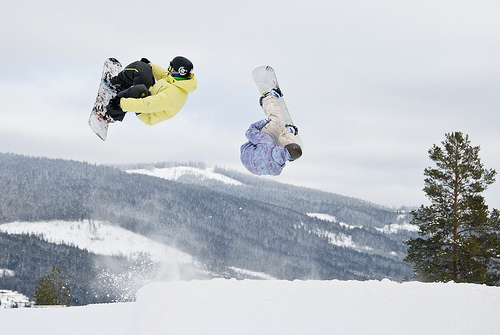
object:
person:
[239, 85, 304, 175]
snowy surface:
[93, 279, 402, 331]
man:
[239, 93, 304, 177]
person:
[102, 55, 199, 126]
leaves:
[405, 132, 497, 282]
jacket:
[119, 61, 196, 126]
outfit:
[89, 56, 198, 139]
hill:
[54, 124, 469, 329]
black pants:
[107, 61, 155, 122]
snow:
[176, 162, 279, 245]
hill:
[3, 105, 352, 330]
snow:
[19, 273, 487, 334]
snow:
[1, 275, 498, 331]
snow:
[125, 277, 361, 334]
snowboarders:
[87, 55, 303, 177]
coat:
[240, 117, 291, 176]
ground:
[3, 157, 492, 333]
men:
[91, 55, 301, 176]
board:
[88, 57, 126, 142]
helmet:
[284, 143, 303, 161]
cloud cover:
[1, 0, 499, 217]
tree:
[217, 233, 230, 245]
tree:
[260, 225, 282, 245]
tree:
[167, 210, 172, 217]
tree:
[182, 187, 193, 206]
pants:
[253, 92, 300, 147]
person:
[107, 52, 196, 130]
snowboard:
[94, 51, 124, 136]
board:
[252, 66, 305, 148]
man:
[102, 56, 196, 127]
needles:
[422, 179, 434, 187]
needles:
[402, 237, 412, 244]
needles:
[402, 252, 412, 263]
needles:
[488, 165, 495, 175]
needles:
[465, 135, 470, 143]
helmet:
[166, 56, 195, 77]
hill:
[0, 154, 499, 308]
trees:
[0, 131, 498, 307]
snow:
[0, 162, 497, 333]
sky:
[333, 27, 383, 71]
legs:
[103, 61, 149, 121]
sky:
[2, 2, 498, 196]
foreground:
[2, 277, 495, 333]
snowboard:
[249, 64, 299, 147]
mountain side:
[334, 281, 484, 332]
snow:
[150, 286, 400, 327]